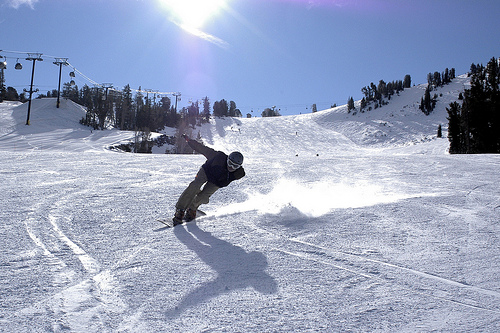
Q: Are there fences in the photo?
A: No, there are no fences.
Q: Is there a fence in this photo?
A: No, there are no fences.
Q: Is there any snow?
A: Yes, there is snow.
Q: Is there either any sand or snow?
A: Yes, there is snow.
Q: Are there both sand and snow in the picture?
A: No, there is snow but no sand.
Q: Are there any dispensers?
A: No, there are no dispensers.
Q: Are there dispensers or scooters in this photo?
A: No, there are no dispensers or scooters.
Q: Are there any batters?
A: No, there are no batters.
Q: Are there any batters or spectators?
A: No, there are no batters or spectators.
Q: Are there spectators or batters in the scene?
A: No, there are no batters or spectators.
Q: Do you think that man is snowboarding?
A: Yes, the man is snowboarding.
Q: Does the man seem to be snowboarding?
A: Yes, the man is snowboarding.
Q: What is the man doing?
A: The man is snowboarding.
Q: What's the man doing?
A: The man is snowboarding.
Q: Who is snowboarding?
A: The man is snowboarding.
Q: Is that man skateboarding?
A: No, the man is snowboarding.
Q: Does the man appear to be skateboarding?
A: No, the man is snowboarding.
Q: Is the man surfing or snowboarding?
A: The man is snowboarding.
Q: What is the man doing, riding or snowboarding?
A: The man is snowboarding.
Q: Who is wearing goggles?
A: The man is wearing goggles.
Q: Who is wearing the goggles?
A: The man is wearing goggles.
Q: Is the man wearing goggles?
A: Yes, the man is wearing goggles.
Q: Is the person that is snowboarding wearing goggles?
A: Yes, the man is wearing goggles.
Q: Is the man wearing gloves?
A: No, the man is wearing goggles.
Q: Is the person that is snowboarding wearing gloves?
A: No, the man is wearing goggles.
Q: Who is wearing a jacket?
A: The man is wearing a jacket.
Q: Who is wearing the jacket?
A: The man is wearing a jacket.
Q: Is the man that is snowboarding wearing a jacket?
A: Yes, the man is wearing a jacket.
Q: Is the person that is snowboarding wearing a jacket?
A: Yes, the man is wearing a jacket.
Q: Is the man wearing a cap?
A: No, the man is wearing a jacket.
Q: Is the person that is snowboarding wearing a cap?
A: No, the man is wearing a jacket.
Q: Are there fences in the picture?
A: No, there are no fences.